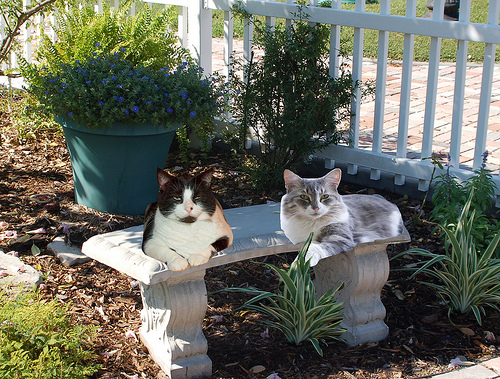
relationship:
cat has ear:
[278, 169, 402, 267] [282, 167, 302, 189]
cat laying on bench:
[278, 169, 402, 267] [81, 194, 413, 377]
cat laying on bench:
[142, 167, 234, 272] [81, 194, 413, 377]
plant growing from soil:
[205, 233, 347, 356] [0, 112, 499, 378]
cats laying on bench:
[141, 166, 401, 273] [81, 194, 413, 377]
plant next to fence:
[14, 2, 220, 162] [1, 0, 498, 201]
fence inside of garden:
[1, 0, 498, 201] [1, 82, 498, 379]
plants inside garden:
[1, 1, 375, 214] [1, 82, 498, 379]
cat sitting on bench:
[278, 169, 402, 267] [81, 194, 413, 377]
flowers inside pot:
[48, 41, 202, 122] [52, 114, 185, 215]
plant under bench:
[205, 233, 347, 356] [81, 194, 413, 377]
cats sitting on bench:
[141, 166, 401, 273] [81, 194, 413, 377]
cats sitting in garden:
[141, 166, 401, 273] [1, 82, 498, 379]